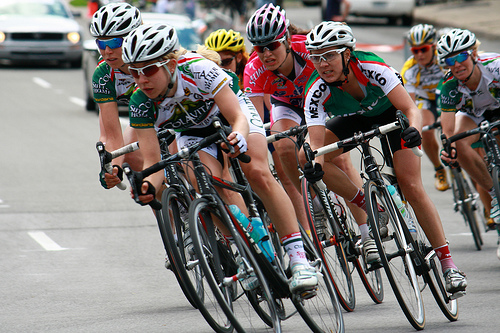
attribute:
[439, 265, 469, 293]
shoe — white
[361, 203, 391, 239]
shoe — white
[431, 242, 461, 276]
sock — red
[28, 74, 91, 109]
markings — white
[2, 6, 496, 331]
road — asphalt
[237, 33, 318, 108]
jersey — red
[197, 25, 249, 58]
helmet — yellow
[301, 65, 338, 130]
jersey sleeve — written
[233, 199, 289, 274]
bottles — blue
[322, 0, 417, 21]
car — back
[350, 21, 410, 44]
road — side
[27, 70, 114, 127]
lines — white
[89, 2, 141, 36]
white helmet — for bike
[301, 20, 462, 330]
racer — bike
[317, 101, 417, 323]
bike — racing